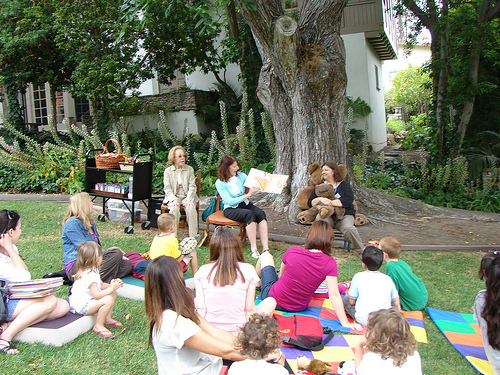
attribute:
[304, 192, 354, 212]
arms — her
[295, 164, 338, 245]
bear — teddy 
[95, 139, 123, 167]
basket — Brown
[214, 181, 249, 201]
sweater — blue 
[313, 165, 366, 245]
lady — holding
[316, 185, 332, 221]
bear —  teddy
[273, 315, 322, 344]
bag — messenger, Red 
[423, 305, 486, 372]
quilt — Multi, colored,  lawn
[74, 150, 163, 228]
cart — Black 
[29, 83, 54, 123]
panes — many 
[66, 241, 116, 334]
girl — Little, listening 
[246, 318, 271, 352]
hair — curly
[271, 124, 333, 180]
trunk — tree,  large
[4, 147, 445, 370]
people — sitting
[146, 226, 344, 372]
adults — sitting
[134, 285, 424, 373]
children — sitting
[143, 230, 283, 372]
children — sitting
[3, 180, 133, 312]
adults — sitting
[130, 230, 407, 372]
children — sitting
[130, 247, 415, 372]
children — sitting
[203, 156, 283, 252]
lady — reading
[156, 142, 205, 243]
woman — sitting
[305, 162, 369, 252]
woman — sitting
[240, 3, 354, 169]
tree — under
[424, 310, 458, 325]
square — blue 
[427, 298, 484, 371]
quilt — patchwork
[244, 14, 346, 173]
tree — brown, large,  trunk 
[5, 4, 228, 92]
leaves — green 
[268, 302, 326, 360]
backpack — red, black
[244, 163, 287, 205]
book — story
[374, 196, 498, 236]
dirt — brown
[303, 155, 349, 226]
bear — giant, brown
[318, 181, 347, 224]
bear — little, brown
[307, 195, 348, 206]
arm's — woman's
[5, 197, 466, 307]
parents — several, at story-time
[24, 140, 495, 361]
children — at story-time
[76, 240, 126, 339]
girl — young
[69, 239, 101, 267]
hair — blonde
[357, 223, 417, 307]
boys — young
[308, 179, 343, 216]
bear — teddy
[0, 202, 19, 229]
hair — black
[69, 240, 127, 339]
daughter — her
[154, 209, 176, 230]
hair — blonde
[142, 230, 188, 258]
shirt — yellow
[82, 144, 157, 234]
cart — black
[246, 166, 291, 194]
book — open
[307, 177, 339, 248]
teddy bear — large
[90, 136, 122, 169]
basket — brown, woven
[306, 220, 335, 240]
hair — brown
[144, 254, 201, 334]
hair — brown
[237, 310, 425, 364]
hair — curly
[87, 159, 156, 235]
cart — black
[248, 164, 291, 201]
book — open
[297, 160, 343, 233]
teddy bear — dark brown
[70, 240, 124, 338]
girl — small, sitting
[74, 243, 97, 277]
hair — blonde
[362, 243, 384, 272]
hair — black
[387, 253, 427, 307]
shirt — green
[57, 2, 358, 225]
tree — big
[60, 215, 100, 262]
shirt — blue